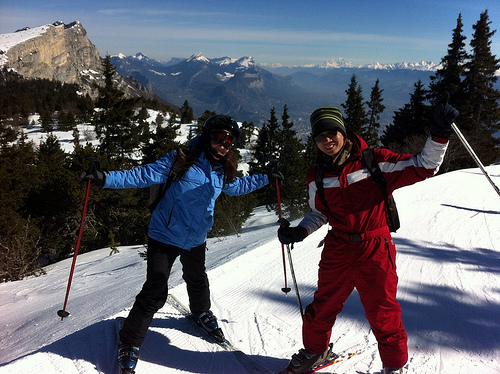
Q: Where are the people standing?
A: On the snow.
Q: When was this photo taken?
A: During the daytime.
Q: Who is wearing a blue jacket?
A: The person on the left.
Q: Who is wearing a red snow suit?
A: The person on the right.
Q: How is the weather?
A: Sunny.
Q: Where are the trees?
A: Behind the skiers.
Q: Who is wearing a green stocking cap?
A: The man in red.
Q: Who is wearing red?
A: Person on right.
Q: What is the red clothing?
A: Ski suit.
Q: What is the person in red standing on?
A: Snow.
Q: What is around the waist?
A: Belt.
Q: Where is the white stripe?
A: Across chest.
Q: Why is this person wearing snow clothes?
A: It's cold.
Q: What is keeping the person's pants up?
A: Belt.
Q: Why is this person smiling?
A: Having fun.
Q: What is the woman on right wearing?
A: A ski outfit.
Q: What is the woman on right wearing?
A: A hat.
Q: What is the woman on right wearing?
A: Sunglasses.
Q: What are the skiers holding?
A: Ski poles.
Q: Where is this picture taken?
A: On a snowy mountain.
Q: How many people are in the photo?
A: Two people.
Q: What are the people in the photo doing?
A: Skiing and posing for a photo.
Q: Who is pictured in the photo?
A: Two women.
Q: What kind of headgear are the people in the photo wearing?
A: One is wearing a helmet and the other is wearing a beanie.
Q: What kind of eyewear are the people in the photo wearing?
A: One is wearing tinted goggles and the other is wearing sun glasses.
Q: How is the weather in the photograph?
A: It is sunny with some clouds in the distance.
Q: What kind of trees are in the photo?
A: Pine trees.